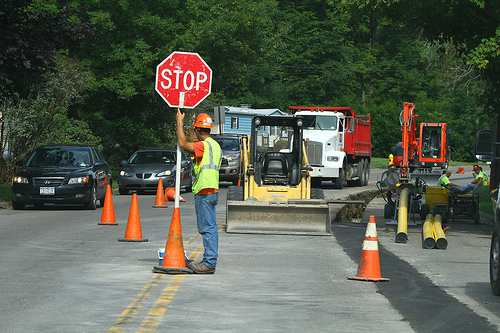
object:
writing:
[158, 70, 206, 92]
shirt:
[190, 139, 222, 196]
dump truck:
[288, 106, 373, 189]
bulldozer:
[222, 114, 333, 237]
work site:
[97, 163, 498, 293]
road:
[0, 165, 499, 332]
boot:
[187, 260, 217, 273]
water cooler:
[155, 247, 193, 269]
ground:
[0, 165, 499, 333]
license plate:
[37, 186, 55, 196]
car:
[10, 143, 117, 211]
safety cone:
[346, 213, 391, 283]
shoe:
[186, 261, 216, 274]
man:
[173, 107, 222, 276]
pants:
[193, 191, 220, 270]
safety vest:
[189, 135, 225, 195]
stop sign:
[153, 49, 213, 108]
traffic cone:
[96, 182, 119, 224]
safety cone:
[117, 194, 149, 243]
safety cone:
[151, 175, 166, 208]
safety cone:
[153, 203, 193, 275]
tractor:
[396, 101, 452, 182]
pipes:
[394, 188, 409, 244]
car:
[116, 149, 198, 196]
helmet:
[188, 112, 215, 129]